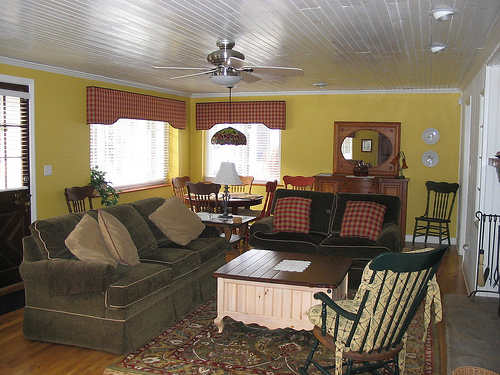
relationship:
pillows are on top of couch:
[57, 211, 147, 281] [23, 178, 243, 353]